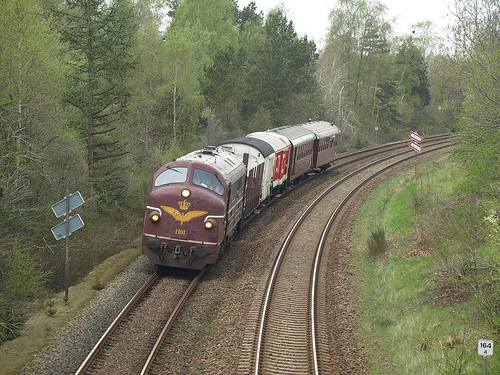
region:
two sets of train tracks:
[67, 76, 483, 371]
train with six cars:
[131, 97, 361, 272]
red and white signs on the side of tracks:
[392, 121, 434, 184]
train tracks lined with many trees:
[15, 0, 387, 314]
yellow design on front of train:
[146, 196, 212, 232]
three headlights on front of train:
[147, 187, 225, 236]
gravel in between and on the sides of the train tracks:
[65, 281, 362, 358]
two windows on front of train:
[147, 165, 233, 192]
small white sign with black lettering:
[468, 333, 493, 369]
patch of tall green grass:
[362, 220, 396, 258]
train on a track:
[141, 110, 341, 278]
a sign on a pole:
[52, 188, 82, 295]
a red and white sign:
[411, 130, 421, 177]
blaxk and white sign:
[478, 340, 491, 356]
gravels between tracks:
[193, 256, 258, 351]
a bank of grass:
[361, 193, 417, 291]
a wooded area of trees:
[9, 4, 145, 243]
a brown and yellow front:
[142, 168, 223, 271]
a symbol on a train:
[153, 199, 214, 233]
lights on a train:
[145, 210, 215, 231]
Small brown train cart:
[305, 104, 352, 181]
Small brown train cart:
[280, 99, 320, 204]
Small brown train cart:
[248, 124, 305, 202]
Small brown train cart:
[205, 128, 297, 235]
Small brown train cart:
[116, 126, 316, 313]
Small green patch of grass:
[376, 334, 408, 370]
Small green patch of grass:
[405, 313, 432, 373]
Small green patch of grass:
[442, 293, 467, 326]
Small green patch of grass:
[376, 239, 483, 349]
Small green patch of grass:
[50, 87, 157, 146]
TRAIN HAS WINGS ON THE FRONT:
[156, 197, 224, 234]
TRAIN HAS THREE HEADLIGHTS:
[141, 189, 241, 232]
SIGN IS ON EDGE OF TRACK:
[400, 121, 425, 167]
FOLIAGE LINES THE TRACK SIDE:
[0, 20, 270, 170]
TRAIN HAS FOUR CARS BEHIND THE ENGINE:
[137, 115, 344, 255]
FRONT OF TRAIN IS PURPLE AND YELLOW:
[142, 156, 231, 276]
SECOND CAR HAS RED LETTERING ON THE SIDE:
[228, 130, 299, 200]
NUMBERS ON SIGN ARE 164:
[474, 337, 499, 360]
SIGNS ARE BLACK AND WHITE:
[406, 125, 431, 167]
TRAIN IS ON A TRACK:
[69, 265, 219, 370]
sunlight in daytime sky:
[265, 0, 486, 48]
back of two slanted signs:
[51, 189, 85, 239]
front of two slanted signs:
[411, 130, 424, 152]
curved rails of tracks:
[76, 135, 460, 373]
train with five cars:
[140, 119, 339, 273]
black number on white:
[477, 338, 494, 355]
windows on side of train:
[293, 134, 339, 159]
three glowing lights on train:
[152, 189, 214, 229]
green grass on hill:
[356, 158, 466, 369]